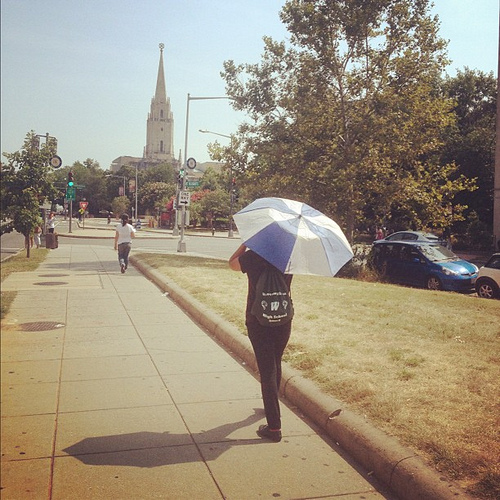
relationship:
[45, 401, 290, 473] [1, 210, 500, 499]
shadow on ground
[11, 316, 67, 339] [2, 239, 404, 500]
manhole on sidewalk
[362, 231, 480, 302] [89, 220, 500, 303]
car on street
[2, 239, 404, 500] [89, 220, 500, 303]
sidewalk by street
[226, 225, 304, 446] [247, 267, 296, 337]
girl wearing backpack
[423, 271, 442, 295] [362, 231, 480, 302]
tire on car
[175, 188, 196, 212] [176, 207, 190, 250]
sign on post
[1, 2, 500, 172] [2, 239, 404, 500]
sky above sidewalk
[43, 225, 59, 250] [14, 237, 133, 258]
disposal on corner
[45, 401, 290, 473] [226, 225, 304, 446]
shadow of girl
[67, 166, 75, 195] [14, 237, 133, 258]
signal at corner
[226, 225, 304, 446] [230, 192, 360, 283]
girl holding umbrella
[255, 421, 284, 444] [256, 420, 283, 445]
shoe on foot